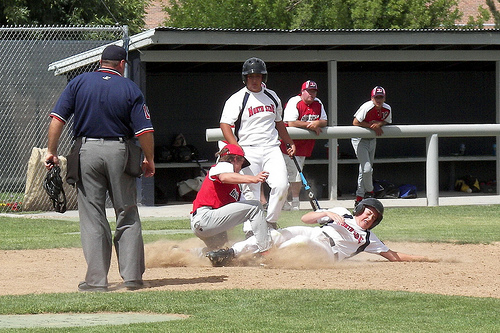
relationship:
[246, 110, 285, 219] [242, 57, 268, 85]
person wearing helmet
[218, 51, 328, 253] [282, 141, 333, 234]
player holding bat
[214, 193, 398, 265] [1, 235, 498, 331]
baseball player sliding dirt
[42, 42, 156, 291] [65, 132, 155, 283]
umpire has pants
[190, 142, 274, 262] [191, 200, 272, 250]
catcher has pants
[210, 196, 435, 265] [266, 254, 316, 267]
player sliding into base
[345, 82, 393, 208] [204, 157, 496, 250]
player on sideline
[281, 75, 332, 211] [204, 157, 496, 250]
player on sideline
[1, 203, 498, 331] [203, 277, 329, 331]
grass around base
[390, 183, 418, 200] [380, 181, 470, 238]
bag on ground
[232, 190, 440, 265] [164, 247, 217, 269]
player sliding into home plate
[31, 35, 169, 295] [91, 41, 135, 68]
umpire has cap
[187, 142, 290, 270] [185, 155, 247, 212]
catcher has shirt